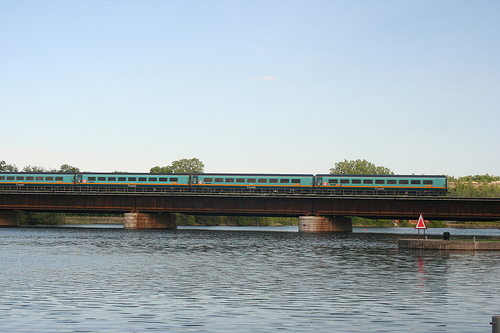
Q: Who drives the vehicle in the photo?
A: Conductor.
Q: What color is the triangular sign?
A: Red.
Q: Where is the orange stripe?
A: Train.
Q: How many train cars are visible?
A: Four.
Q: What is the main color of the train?
A: Green.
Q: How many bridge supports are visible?
A: Two.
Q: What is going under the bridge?
A: Water.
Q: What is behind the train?
A: Trees.